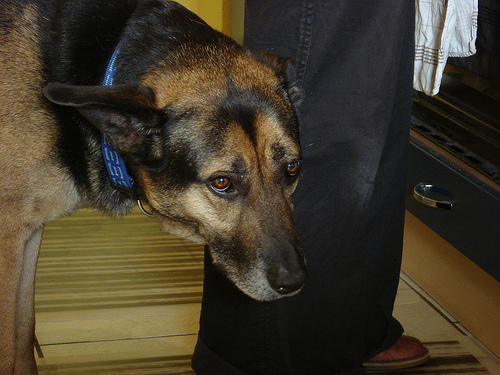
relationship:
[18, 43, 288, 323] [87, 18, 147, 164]
dog with collar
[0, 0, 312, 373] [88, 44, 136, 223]
dog wearing collar